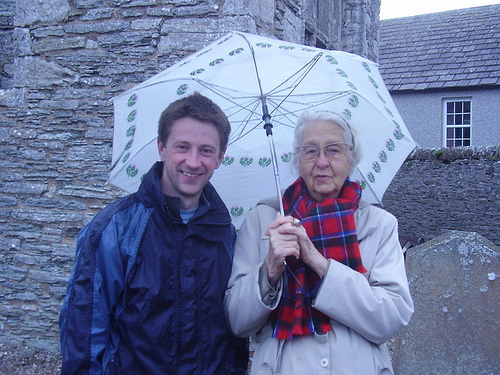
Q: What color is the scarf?
A: Red and blue.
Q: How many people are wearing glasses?
A: One.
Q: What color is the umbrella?
A: White.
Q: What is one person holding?
A: An umbrella.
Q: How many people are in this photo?
A: Two.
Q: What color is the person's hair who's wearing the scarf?
A: White.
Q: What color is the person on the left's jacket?
A: Blue.